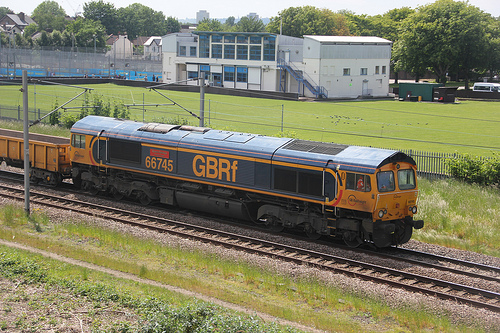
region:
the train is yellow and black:
[91, 95, 416, 199]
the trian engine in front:
[121, 98, 418, 245]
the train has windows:
[330, 163, 420, 191]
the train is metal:
[142, 153, 472, 251]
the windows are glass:
[370, 165, 478, 206]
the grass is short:
[143, 300, 190, 326]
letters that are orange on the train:
[188, 152, 238, 187]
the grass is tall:
[443, 197, 478, 227]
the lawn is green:
[420, 113, 485, 139]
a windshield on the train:
[376, 173, 399, 188]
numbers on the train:
[142, 152, 172, 174]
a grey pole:
[21, 81, 33, 207]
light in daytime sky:
[1, 0, 497, 18]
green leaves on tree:
[396, 1, 485, 75]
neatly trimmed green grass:
[0, 80, 498, 173]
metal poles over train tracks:
[22, 69, 206, 219]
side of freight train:
[0, 115, 417, 252]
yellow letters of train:
[191, 154, 238, 181]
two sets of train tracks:
[0, 158, 499, 310]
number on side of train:
[143, 156, 174, 172]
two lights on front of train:
[378, 206, 418, 218]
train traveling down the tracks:
[0, 112, 412, 247]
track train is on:
[8, 158, 499, 286]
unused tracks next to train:
[4, 177, 499, 316]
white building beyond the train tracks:
[150, 23, 386, 103]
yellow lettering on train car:
[184, 146, 241, 181]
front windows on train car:
[377, 170, 411, 190]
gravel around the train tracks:
[0, 173, 498, 316]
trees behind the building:
[9, 2, 499, 87]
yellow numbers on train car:
[142, 152, 172, 173]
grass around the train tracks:
[2, 127, 493, 332]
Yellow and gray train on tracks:
[1, 113, 439, 249]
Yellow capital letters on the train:
[181, 148, 248, 193]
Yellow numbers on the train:
[138, 148, 178, 180]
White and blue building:
[157, 29, 403, 101]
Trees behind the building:
[3, 0, 499, 80]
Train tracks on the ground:
[1, 165, 498, 311]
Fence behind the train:
[374, 147, 499, 188]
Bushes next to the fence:
[434, 146, 499, 190]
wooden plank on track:
[115, 205, 130, 226]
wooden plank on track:
[136, 211, 153, 222]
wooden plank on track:
[159, 221, 176, 236]